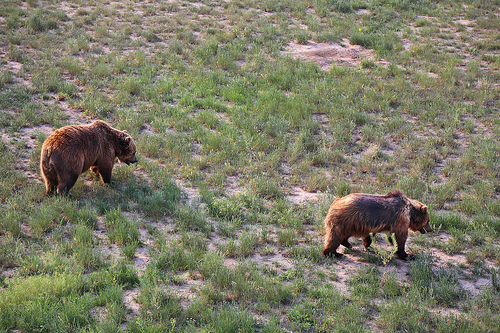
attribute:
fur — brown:
[346, 200, 378, 220]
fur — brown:
[351, 192, 388, 224]